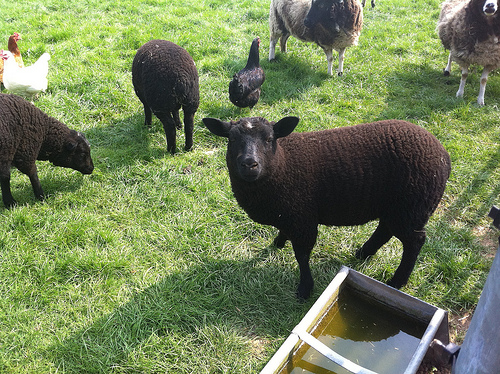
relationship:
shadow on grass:
[42, 251, 366, 372] [1, 2, 499, 372]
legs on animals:
[441, 47, 498, 117] [236, 20, 482, 241]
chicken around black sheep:
[229, 35, 266, 112] [202, 115, 452, 304]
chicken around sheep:
[229, 35, 266, 112] [432, 7, 499, 96]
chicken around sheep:
[229, 35, 266, 112] [276, 1, 365, 68]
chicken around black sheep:
[229, 35, 266, 112] [131, 38, 201, 154]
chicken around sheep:
[229, 35, 266, 112] [2, 92, 99, 197]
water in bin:
[312, 280, 428, 372] [258, 263, 450, 372]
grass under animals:
[1, 2, 499, 372] [227, 37, 264, 113]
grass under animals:
[1, 2, 499, 372] [200, 115, 451, 296]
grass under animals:
[1, 2, 499, 372] [0, 49, 53, 104]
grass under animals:
[1, 2, 499, 372] [130, 39, 200, 155]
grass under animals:
[1, 2, 499, 372] [0, 93, 94, 207]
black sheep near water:
[204, 103, 455, 290] [278, 275, 432, 372]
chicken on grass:
[231, 36, 266, 105] [1, 2, 499, 372]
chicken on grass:
[0, 51, 56, 102] [72, 31, 132, 122]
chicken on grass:
[0, 48, 52, 104] [63, 211, 194, 293]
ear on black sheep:
[272, 115, 299, 138] [200, 115, 450, 297]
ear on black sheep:
[200, 117, 229, 134] [200, 115, 450, 297]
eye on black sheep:
[263, 132, 275, 143] [202, 115, 452, 304]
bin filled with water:
[240, 260, 450, 371] [336, 313, 398, 350]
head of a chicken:
[8, 30, 22, 51] [3, 30, 52, 101]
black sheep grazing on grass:
[202, 115, 452, 304] [94, 234, 216, 325]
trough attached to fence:
[433, 239, 499, 372] [250, 264, 449, 371]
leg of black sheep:
[288, 229, 319, 298] [202, 115, 452, 304]